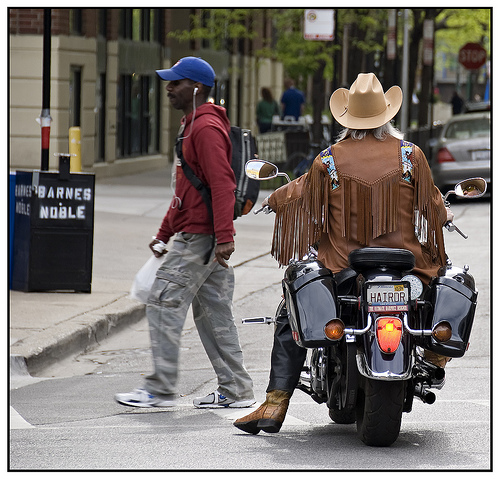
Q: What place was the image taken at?
A: It was taken at the city.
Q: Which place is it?
A: It is a city.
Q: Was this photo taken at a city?
A: Yes, it was taken in a city.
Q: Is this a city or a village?
A: It is a city.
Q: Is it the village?
A: No, it is the city.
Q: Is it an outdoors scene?
A: Yes, it is outdoors.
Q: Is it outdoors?
A: Yes, it is outdoors.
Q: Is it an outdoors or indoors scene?
A: It is outdoors.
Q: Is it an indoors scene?
A: No, it is outdoors.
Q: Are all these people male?
A: No, they are both male and female.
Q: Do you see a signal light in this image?
A: No, there are no traffic lights.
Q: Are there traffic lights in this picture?
A: No, there are no traffic lights.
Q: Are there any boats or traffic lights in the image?
A: No, there are no traffic lights or boats.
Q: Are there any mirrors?
A: Yes, there is a mirror.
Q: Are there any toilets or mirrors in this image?
A: Yes, there is a mirror.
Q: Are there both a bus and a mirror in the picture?
A: No, there is a mirror but no buses.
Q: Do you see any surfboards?
A: No, there are no surfboards.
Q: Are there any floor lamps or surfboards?
A: No, there are no surfboards or floor lamps.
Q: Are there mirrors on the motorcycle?
A: Yes, there is a mirror on the motorcycle.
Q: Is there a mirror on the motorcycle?
A: Yes, there is a mirror on the motorcycle.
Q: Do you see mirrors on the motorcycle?
A: Yes, there is a mirror on the motorcycle.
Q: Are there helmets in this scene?
A: No, there are no helmets.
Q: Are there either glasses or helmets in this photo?
A: No, there are no helmets or glasses.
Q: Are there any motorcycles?
A: Yes, there is a motorcycle.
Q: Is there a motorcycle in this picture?
A: Yes, there is a motorcycle.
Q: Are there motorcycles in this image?
A: Yes, there is a motorcycle.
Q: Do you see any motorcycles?
A: Yes, there is a motorcycle.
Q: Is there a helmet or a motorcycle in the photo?
A: Yes, there is a motorcycle.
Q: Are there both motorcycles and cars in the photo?
A: Yes, there are both a motorcycle and a car.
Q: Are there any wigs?
A: No, there are no wigs.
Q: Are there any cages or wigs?
A: No, there are no wigs or cages.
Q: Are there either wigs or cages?
A: No, there are no wigs or cages.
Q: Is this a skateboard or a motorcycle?
A: This is a motorcycle.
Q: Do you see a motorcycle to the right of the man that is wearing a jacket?
A: Yes, there is a motorcycle to the right of the man.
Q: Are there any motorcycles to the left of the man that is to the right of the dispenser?
A: No, the motorcycle is to the right of the man.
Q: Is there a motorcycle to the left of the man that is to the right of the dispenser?
A: No, the motorcycle is to the right of the man.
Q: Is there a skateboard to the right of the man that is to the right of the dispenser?
A: No, there is a motorcycle to the right of the man.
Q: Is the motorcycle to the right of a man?
A: Yes, the motorcycle is to the right of a man.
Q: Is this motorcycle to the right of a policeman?
A: No, the motorcycle is to the right of a man.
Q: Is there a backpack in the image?
A: Yes, there is a backpack.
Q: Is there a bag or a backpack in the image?
A: Yes, there is a backpack.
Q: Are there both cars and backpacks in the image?
A: Yes, there are both a backpack and a car.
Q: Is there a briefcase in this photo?
A: No, there are no briefcases.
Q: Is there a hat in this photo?
A: Yes, there is a hat.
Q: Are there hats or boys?
A: Yes, there is a hat.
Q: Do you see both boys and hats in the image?
A: No, there is a hat but no boys.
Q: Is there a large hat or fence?
A: Yes, there is a large hat.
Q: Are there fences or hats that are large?
A: Yes, the hat is large.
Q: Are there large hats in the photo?
A: Yes, there is a large hat.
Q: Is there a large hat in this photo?
A: Yes, there is a large hat.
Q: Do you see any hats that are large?
A: Yes, there is a hat that is large.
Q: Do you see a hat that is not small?
A: Yes, there is a large hat.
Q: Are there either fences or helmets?
A: No, there are no helmets or fences.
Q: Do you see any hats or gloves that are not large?
A: No, there is a hat but it is large.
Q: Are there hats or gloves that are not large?
A: No, there is a hat but it is large.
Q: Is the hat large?
A: Yes, the hat is large.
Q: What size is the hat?
A: The hat is large.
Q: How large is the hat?
A: The hat is large.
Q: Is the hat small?
A: No, the hat is large.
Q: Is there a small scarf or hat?
A: No, there is a hat but it is large.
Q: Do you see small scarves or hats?
A: No, there is a hat but it is large.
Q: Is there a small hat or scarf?
A: No, there is a hat but it is large.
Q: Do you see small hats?
A: No, there is a hat but it is large.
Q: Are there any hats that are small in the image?
A: No, there is a hat but it is large.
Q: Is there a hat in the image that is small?
A: No, there is a hat but it is large.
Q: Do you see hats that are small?
A: No, there is a hat but it is large.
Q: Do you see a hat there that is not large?
A: No, there is a hat but it is large.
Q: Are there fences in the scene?
A: No, there are no fences.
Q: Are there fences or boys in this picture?
A: No, there are no fences or boys.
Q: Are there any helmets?
A: No, there are no helmets.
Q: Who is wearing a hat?
A: The man is wearing a hat.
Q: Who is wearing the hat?
A: The man is wearing a hat.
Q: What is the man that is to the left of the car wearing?
A: The man is wearing a hat.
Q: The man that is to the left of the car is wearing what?
A: The man is wearing a hat.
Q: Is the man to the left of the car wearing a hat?
A: Yes, the man is wearing a hat.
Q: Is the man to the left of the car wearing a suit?
A: No, the man is wearing a hat.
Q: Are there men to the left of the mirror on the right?
A: Yes, there is a man to the left of the mirror.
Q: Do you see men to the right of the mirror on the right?
A: No, the man is to the left of the mirror.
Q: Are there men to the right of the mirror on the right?
A: No, the man is to the left of the mirror.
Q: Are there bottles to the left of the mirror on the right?
A: No, there is a man to the left of the mirror.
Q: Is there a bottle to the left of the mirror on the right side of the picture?
A: No, there is a man to the left of the mirror.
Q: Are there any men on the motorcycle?
A: Yes, there is a man on the motorcycle.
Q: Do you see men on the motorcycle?
A: Yes, there is a man on the motorcycle.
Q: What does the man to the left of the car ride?
A: The man rides a motorcycle.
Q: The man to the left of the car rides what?
A: The man rides a motorcycle.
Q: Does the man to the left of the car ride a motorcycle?
A: Yes, the man rides a motorcycle.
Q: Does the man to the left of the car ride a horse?
A: No, the man rides a motorcycle.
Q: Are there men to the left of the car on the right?
A: Yes, there is a man to the left of the car.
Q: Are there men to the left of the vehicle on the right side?
A: Yes, there is a man to the left of the car.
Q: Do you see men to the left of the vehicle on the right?
A: Yes, there is a man to the left of the car.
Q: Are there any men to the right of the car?
A: No, the man is to the left of the car.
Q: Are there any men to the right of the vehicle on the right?
A: No, the man is to the left of the car.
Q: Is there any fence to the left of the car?
A: No, there is a man to the left of the car.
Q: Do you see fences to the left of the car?
A: No, there is a man to the left of the car.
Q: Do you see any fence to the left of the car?
A: No, there is a man to the left of the car.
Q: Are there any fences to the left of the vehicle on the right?
A: No, there is a man to the left of the car.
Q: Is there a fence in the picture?
A: No, there are no fences.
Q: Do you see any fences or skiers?
A: No, there are no fences or skiers.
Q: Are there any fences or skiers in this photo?
A: No, there are no fences or skiers.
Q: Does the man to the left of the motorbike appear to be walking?
A: Yes, the man is walking.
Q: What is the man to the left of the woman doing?
A: The man is walking.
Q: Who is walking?
A: The man is walking.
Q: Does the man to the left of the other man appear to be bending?
A: No, the man is walking.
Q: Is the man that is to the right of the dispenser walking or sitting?
A: The man is walking.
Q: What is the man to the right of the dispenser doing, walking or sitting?
A: The man is walking.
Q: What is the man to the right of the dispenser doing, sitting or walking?
A: The man is walking.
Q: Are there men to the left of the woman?
A: Yes, there is a man to the left of the woman.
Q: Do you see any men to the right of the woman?
A: No, the man is to the left of the woman.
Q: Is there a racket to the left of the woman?
A: No, there is a man to the left of the woman.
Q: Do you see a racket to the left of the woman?
A: No, there is a man to the left of the woman.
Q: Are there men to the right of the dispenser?
A: Yes, there is a man to the right of the dispenser.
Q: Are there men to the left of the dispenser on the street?
A: No, the man is to the right of the dispenser.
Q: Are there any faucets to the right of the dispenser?
A: No, there is a man to the right of the dispenser.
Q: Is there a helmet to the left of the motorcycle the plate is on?
A: No, there is a man to the left of the motorcycle.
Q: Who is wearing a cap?
A: The man is wearing a cap.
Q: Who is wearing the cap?
A: The man is wearing a cap.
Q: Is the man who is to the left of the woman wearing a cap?
A: Yes, the man is wearing a cap.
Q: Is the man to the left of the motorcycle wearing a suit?
A: No, the man is wearing a cap.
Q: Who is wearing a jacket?
A: The man is wearing a jacket.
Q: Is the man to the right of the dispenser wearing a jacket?
A: Yes, the man is wearing a jacket.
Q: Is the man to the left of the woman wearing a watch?
A: No, the man is wearing a jacket.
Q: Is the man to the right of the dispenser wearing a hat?
A: Yes, the man is wearing a hat.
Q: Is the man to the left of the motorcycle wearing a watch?
A: No, the man is wearing a hat.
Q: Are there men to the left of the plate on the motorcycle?
A: Yes, there is a man to the left of the plate.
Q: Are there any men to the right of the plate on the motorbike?
A: No, the man is to the left of the plate.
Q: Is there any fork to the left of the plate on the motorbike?
A: No, there is a man to the left of the plate.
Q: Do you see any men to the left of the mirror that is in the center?
A: Yes, there is a man to the left of the mirror.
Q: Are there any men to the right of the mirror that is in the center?
A: No, the man is to the left of the mirror.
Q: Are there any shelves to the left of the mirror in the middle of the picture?
A: No, there is a man to the left of the mirror.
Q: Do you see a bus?
A: No, there are no buses.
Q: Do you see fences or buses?
A: No, there are no buses or fences.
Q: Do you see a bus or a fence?
A: No, there are no buses or fences.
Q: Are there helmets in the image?
A: No, there are no helmets.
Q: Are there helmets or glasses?
A: No, there are no helmets or glasses.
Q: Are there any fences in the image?
A: No, there are no fences.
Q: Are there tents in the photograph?
A: No, there are no tents.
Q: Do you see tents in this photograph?
A: No, there are no tents.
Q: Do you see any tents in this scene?
A: No, there are no tents.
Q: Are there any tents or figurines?
A: No, there are no tents or figurines.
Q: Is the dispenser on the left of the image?
A: Yes, the dispenser is on the left of the image.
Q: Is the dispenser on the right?
A: No, the dispenser is on the left of the image.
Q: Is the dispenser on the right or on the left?
A: The dispenser is on the left of the image.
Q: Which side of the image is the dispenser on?
A: The dispenser is on the left of the image.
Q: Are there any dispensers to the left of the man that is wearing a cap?
A: Yes, there is a dispenser to the left of the man.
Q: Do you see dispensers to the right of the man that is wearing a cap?
A: No, the dispenser is to the left of the man.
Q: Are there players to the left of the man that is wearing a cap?
A: No, there is a dispenser to the left of the man.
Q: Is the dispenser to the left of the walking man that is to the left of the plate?
A: Yes, the dispenser is to the left of the man.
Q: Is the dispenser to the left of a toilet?
A: No, the dispenser is to the left of the man.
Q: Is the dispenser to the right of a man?
A: No, the dispenser is to the left of a man.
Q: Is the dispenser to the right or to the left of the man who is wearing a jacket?
A: The dispenser is to the left of the man.